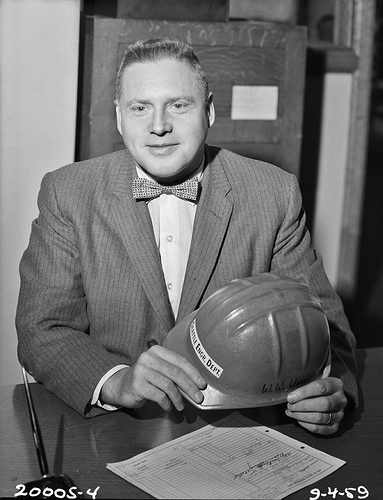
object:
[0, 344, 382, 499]
desk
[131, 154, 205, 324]
shirt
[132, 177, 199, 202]
bow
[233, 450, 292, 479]
lettering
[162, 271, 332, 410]
hat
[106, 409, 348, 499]
invoice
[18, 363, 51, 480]
pen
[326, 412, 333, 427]
band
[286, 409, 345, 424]
finger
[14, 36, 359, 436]
man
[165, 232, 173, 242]
buttons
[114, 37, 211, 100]
hair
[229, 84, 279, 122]
label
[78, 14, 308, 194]
box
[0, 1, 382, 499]
photo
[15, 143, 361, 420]
blazer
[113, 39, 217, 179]
head